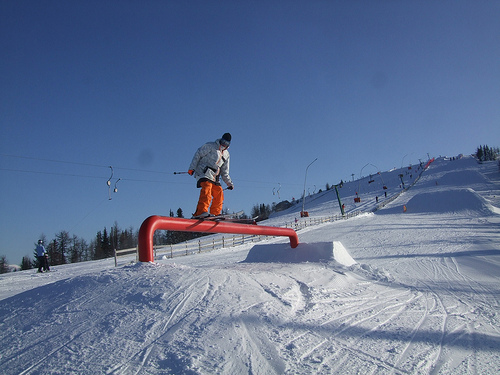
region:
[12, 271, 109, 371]
white snow with streaks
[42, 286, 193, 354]
white snow with streakswhite snow with streaks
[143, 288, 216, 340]
white snow with streaks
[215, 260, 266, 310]
white snow with streaks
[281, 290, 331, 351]
white snow with streaks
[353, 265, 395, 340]
white snow with streaks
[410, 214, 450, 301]
white snow with streaks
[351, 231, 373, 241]
white snow with streaks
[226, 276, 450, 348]
white snow with streaks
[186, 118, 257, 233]
a man grinding with skis on a red pole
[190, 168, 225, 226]
orange ski pants on a man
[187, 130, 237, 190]
a white and black jacket on a man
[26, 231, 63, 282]
a person skiing with their child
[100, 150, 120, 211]
an empty ski left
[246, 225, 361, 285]
a ramp in the snow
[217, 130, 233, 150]
a black beanie on a skier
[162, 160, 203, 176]
a ski pole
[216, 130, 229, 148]
ski goggles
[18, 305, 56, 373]
white snow touched by boards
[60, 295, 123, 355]
white snow touched by boards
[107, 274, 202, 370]
white snow touched by boards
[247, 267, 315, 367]
white snow touched by boards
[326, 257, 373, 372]
white snow touched by boards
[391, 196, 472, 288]
white snow touched by boards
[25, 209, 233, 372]
white snow touched by boards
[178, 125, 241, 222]
ATHLETIC PERSON ON SKI SLOPE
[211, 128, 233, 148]
HEAD OF ATHLETIC PERSON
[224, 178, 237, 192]
HAND OF ATHLETIC PERSON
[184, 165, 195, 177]
HAND OF ATHLETIC PERSON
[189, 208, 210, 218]
FOOT OF ATHLETIC PERSON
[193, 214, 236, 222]
PART OF PERSON'S SKLIS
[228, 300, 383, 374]
SKI TRACKS IN SNOW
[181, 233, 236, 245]
WOODEN FENCE ALONG TRAIL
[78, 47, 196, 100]
CLEAR BLUE WINTER SKY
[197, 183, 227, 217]
ORANGE PANTS OF PERSON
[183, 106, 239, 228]
man on red pipe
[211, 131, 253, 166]
man has black hat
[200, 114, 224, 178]
man has grey coat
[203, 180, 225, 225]
man has orange pants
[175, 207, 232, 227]
man on white skis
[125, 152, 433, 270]
rail behind ski track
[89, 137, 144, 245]
ski lift on wires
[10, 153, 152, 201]
black wires in sky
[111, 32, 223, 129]
blue and clear sky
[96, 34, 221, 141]
no clouds in sky